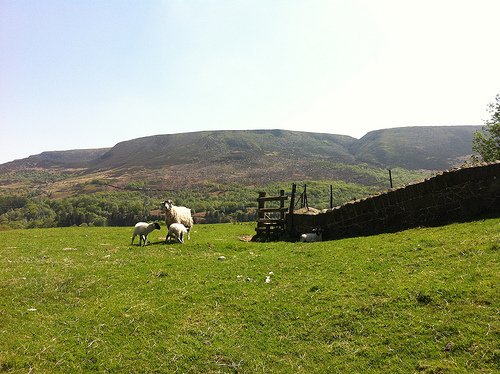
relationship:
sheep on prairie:
[129, 219, 160, 246] [6, 219, 498, 371]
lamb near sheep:
[162, 220, 192, 244] [157, 196, 195, 233]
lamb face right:
[129, 217, 162, 246] [434, 6, 480, 372]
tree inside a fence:
[463, 88, 499, 162] [249, 157, 496, 236]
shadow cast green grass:
[147, 237, 177, 247] [6, 219, 498, 371]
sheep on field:
[157, 196, 195, 233] [6, 219, 498, 371]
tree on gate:
[463, 88, 499, 162] [249, 157, 496, 236]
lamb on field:
[129, 217, 162, 246] [6, 219, 498, 371]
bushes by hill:
[15, 166, 363, 203] [7, 123, 493, 199]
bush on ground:
[9, 201, 59, 233] [2, 228, 89, 253]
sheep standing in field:
[157, 196, 195, 233] [6, 219, 498, 371]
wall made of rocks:
[249, 157, 496, 236] [291, 161, 498, 255]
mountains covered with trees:
[7, 123, 493, 199] [15, 166, 363, 203]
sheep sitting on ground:
[162, 220, 192, 244] [6, 219, 498, 371]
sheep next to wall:
[157, 196, 195, 233] [249, 157, 496, 236]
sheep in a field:
[157, 196, 195, 233] [6, 219, 498, 371]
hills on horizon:
[7, 123, 493, 199] [7, 125, 486, 146]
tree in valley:
[7, 192, 140, 224] [15, 166, 363, 203]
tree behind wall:
[463, 88, 499, 162] [249, 157, 496, 236]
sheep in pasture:
[157, 196, 195, 233] [6, 219, 498, 371]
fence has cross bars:
[250, 181, 311, 244] [254, 185, 292, 241]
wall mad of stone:
[291, 161, 498, 255] [249, 157, 496, 236]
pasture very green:
[9, 226, 477, 361] [6, 219, 498, 371]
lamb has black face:
[129, 217, 162, 246] [150, 217, 164, 231]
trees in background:
[7, 123, 493, 199] [0, 4, 497, 128]